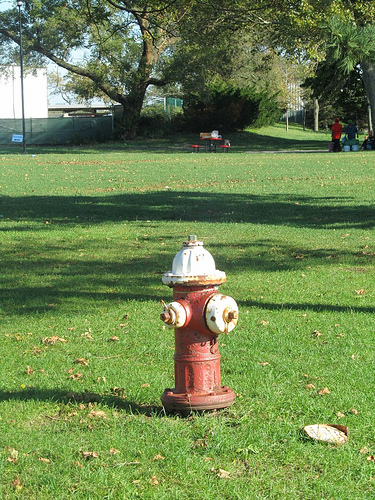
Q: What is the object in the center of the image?
A: Fire hydrant.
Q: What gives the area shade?
A: Trees.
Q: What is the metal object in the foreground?
A: Hydrant.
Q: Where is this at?
A: Park.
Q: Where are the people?
A: Under the trees.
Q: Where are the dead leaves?
A: On the grass.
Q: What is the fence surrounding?
A: The park.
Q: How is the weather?
A: Nice and clear.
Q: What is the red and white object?
A: Hydrant.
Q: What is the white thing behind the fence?
A: A building.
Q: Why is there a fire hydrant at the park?
A: To put out fires.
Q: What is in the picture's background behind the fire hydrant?
A: Red picnic table.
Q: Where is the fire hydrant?
A: Top of the ground in a park.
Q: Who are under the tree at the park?
A: Family with children.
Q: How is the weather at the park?
A: Warm and sunny.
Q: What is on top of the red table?
A: Food.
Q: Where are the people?
A: Standing under a tree.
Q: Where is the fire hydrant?
A: In the grass.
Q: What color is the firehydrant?
A: White and red.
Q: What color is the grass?
A: Green.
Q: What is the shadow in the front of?
A: The fire hydrant.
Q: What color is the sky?
A: Blue.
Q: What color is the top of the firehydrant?
A: White.